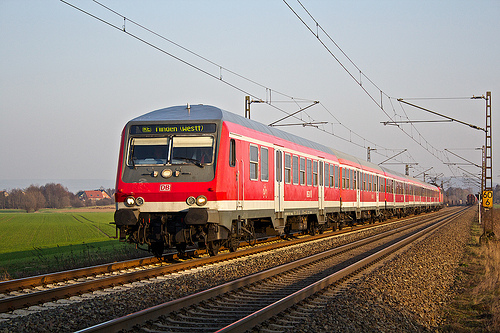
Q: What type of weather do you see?
A: It is cloudless.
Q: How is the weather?
A: It is cloudless.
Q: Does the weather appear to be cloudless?
A: Yes, it is cloudless.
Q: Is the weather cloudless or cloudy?
A: It is cloudless.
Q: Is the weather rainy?
A: No, it is cloudless.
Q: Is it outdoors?
A: Yes, it is outdoors.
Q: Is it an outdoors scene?
A: Yes, it is outdoors.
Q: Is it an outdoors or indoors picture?
A: It is outdoors.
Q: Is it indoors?
A: No, it is outdoors.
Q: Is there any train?
A: Yes, there is a train.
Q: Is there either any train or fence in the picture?
A: Yes, there is a train.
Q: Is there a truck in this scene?
A: No, there are no trucks.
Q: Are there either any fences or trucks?
A: No, there are no trucks or fences.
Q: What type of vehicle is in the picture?
A: The vehicle is a train.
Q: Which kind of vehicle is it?
A: The vehicle is a train.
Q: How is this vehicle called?
A: That is a train.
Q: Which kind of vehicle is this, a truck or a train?
A: That is a train.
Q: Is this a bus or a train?
A: This is a train.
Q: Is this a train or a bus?
A: This is a train.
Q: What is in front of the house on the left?
A: The train is in front of the house.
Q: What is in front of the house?
A: The train is in front of the house.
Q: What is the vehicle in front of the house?
A: The vehicle is a train.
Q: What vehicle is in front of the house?
A: The vehicle is a train.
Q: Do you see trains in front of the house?
A: Yes, there is a train in front of the house.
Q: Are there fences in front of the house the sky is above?
A: No, there is a train in front of the house.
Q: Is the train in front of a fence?
A: No, the train is in front of the house.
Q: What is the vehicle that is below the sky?
A: The vehicle is a train.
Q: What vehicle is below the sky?
A: The vehicle is a train.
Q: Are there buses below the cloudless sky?
A: No, there is a train below the sky.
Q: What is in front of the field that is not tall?
A: The train is in front of the field.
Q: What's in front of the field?
A: The train is in front of the field.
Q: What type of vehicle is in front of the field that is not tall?
A: The vehicle is a train.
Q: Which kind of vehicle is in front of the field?
A: The vehicle is a train.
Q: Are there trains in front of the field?
A: Yes, there is a train in front of the field.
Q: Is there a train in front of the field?
A: Yes, there is a train in front of the field.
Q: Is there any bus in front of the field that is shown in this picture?
A: No, there is a train in front of the field.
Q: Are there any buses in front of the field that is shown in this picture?
A: No, there is a train in front of the field.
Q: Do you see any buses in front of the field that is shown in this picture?
A: No, there is a train in front of the field.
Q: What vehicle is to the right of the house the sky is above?
A: The vehicle is a train.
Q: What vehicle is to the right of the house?
A: The vehicle is a train.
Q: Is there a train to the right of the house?
A: Yes, there is a train to the right of the house.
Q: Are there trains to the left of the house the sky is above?
A: No, the train is to the right of the house.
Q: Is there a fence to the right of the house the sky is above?
A: No, there is a train to the right of the house.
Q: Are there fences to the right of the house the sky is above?
A: No, there is a train to the right of the house.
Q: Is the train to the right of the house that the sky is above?
A: Yes, the train is to the right of the house.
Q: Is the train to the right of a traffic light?
A: No, the train is to the right of the house.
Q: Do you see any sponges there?
A: No, there are no sponges.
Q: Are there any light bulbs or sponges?
A: No, there are no sponges or light bulbs.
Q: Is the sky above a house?
A: Yes, the sky is above a house.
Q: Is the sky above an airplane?
A: No, the sky is above a house.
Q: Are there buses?
A: No, there are no buses.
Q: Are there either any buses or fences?
A: No, there are no buses or fences.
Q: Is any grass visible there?
A: Yes, there is grass.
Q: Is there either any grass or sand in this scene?
A: Yes, there is grass.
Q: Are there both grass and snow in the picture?
A: No, there is grass but no snow.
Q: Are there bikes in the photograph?
A: No, there are no bikes.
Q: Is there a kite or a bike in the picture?
A: No, there are no bikes or kites.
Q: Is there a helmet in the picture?
A: No, there are no helmets.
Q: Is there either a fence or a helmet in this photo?
A: No, there are no helmets or fences.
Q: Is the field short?
A: Yes, the field is short.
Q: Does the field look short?
A: Yes, the field is short.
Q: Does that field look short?
A: Yes, the field is short.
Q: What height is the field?
A: The field is short.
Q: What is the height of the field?
A: The field is short.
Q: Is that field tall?
A: No, the field is short.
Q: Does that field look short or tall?
A: The field is short.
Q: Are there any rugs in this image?
A: No, there are no rugs.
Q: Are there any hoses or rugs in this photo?
A: No, there are no rugs or hoses.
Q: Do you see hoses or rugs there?
A: No, there are no rugs or hoses.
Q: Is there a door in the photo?
A: Yes, there are doors.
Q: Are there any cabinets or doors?
A: Yes, there are doors.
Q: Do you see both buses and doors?
A: No, there are doors but no buses.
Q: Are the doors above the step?
A: Yes, the doors are above the step.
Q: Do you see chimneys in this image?
A: No, there are no chimneys.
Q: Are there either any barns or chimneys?
A: No, there are no chimneys or barns.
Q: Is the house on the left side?
A: Yes, the house is on the left of the image.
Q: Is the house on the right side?
A: No, the house is on the left of the image.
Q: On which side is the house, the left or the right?
A: The house is on the left of the image.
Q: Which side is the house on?
A: The house is on the left of the image.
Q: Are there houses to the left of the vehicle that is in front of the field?
A: Yes, there is a house to the left of the train.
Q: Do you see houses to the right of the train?
A: No, the house is to the left of the train.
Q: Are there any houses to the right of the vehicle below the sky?
A: No, the house is to the left of the train.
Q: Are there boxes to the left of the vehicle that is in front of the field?
A: No, there is a house to the left of the train.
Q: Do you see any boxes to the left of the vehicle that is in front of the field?
A: No, there is a house to the left of the train.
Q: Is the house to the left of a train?
A: Yes, the house is to the left of a train.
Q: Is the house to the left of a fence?
A: No, the house is to the left of a train.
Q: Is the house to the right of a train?
A: No, the house is to the left of a train.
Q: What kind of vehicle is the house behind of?
A: The house is behind the train.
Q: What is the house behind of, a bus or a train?
A: The house is behind a train.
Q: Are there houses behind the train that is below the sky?
A: Yes, there is a house behind the train.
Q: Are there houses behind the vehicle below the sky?
A: Yes, there is a house behind the train.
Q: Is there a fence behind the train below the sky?
A: No, there is a house behind the train.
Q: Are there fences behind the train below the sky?
A: No, there is a house behind the train.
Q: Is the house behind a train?
A: Yes, the house is behind a train.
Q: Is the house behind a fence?
A: No, the house is behind a train.